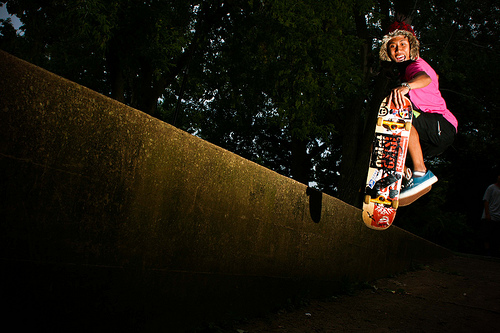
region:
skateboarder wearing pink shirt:
[374, 23, 463, 209]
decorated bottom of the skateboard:
[362, 88, 404, 229]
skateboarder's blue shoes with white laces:
[395, 168, 446, 208]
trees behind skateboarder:
[5, 2, 495, 217]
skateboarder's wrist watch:
[397, 80, 408, 95]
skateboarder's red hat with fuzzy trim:
[375, 17, 415, 67]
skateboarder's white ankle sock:
[411, 167, 426, 175]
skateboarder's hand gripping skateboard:
[385, 82, 407, 110]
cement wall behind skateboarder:
[0, 52, 492, 322]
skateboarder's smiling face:
[388, 34, 412, 69]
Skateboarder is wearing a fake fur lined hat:
[371, 14, 424, 71]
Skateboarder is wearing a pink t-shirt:
[397, 62, 465, 129]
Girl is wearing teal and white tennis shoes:
[399, 169, 436, 209]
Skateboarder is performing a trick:
[350, 17, 469, 252]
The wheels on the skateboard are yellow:
[364, 191, 401, 211]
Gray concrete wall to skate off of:
[128, 101, 324, 321]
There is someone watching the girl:
[475, 163, 498, 238]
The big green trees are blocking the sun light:
[32, 0, 370, 137]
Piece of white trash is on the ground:
[298, 305, 316, 320]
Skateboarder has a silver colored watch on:
[398, 79, 415, 92]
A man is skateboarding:
[341, 19, 474, 256]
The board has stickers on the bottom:
[353, 66, 417, 248]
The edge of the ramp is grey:
[20, 53, 442, 315]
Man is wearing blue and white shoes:
[379, 151, 446, 210]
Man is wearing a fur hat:
[353, 11, 443, 113]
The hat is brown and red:
[365, 18, 442, 87]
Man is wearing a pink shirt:
[361, 41, 466, 164]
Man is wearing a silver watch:
[393, 78, 421, 98]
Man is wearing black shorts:
[351, 21, 463, 200]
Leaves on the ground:
[286, 238, 450, 329]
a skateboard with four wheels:
[340, 86, 427, 251]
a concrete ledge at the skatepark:
[121, 82, 286, 242]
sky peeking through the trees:
[178, 58, 300, 128]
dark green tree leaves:
[274, 20, 371, 123]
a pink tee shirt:
[381, 57, 470, 134]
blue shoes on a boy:
[373, 165, 450, 228]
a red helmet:
[374, 13, 441, 50]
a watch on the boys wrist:
[392, 70, 424, 97]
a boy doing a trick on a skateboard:
[350, 17, 489, 249]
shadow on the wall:
[297, 183, 338, 235]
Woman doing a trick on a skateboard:
[371, 26, 441, 223]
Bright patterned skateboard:
[372, 83, 402, 235]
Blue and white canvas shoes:
[387, 153, 443, 200]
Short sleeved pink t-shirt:
[395, 56, 450, 111]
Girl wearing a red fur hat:
[372, 23, 457, 225]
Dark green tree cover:
[102, 18, 377, 175]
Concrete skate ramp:
[33, 60, 380, 295]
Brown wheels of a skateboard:
[364, 187, 403, 211]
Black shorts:
[409, 105, 466, 155]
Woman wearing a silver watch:
[370, 30, 463, 215]